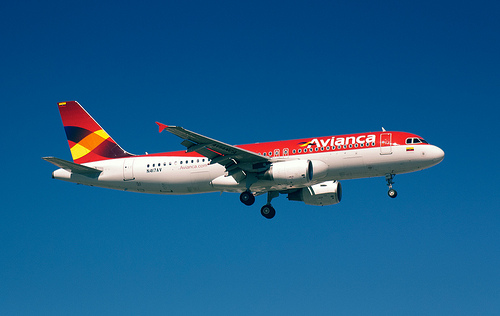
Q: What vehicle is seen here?
A: Airplane.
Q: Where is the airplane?
A: Flying in the air.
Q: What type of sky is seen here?
A: Clear blue sky.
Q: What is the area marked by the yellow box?
A: Blue sky.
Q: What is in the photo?
A: A plane flying through the sky.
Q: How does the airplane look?
A: The airplane is red and white.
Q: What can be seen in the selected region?
A: Landing gear of the plane.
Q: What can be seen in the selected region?
A: Wheels of the plane.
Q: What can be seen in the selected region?
A: Clear blue sky below the plane.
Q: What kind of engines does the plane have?
A: Twin engines.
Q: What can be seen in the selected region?
A: Wing of the plane.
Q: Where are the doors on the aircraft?
A: At the front and the rear.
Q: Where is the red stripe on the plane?
A: On the top portion.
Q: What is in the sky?
A: A plane.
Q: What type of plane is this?
A: A jet.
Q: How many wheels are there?
A: Three.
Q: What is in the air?
A: An airplane.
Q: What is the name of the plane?
A: Avianca.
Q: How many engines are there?
A: Two.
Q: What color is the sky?
A: Blue.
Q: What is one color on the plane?
A: Red.